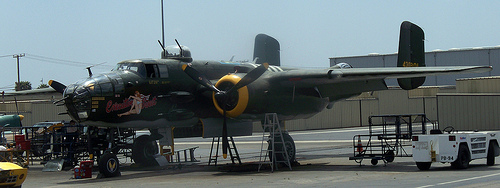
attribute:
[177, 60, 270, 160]
propeller — in the picture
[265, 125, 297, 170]
wheel — in the picture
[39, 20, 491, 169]
plane — in the picture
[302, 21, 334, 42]
clouds — in the picture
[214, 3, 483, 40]
sky — in the picture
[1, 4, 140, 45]
blue sky — in the picture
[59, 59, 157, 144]
nose — in the picture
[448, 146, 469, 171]
wheel — in the picture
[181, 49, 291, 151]
plane propeller — in the picture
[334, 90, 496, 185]
cargo carrier — in the picture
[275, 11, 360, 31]
clouds — in the picture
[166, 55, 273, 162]
propeller — in the picture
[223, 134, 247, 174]
ladder — tall, grey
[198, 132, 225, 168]
ladder — grey, tall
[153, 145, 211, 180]
ladder — grey, tall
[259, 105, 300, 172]
ladder — grey, tall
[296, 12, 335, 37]
sky — clear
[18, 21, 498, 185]
airport — in the picture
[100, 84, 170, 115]
logo — in the picture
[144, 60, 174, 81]
window — in the picture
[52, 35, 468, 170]
airplane — in the picture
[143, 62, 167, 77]
window — in the picture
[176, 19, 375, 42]
sky — in the picture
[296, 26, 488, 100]
wing — in the picture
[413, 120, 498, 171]
cargo carrier — white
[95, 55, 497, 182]
runway — in the picture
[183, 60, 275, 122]
plane engine — yellow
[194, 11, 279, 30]
sky — clear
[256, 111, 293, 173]
ladder — in the picture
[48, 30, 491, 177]
airplane — in the picture